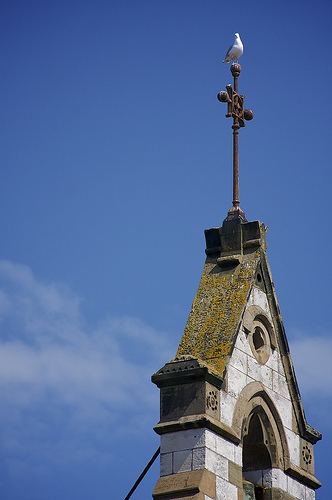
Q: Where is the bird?
A: On top of the cross.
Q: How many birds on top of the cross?
A: One.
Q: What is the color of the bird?
A: White.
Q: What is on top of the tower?
A: A cross.